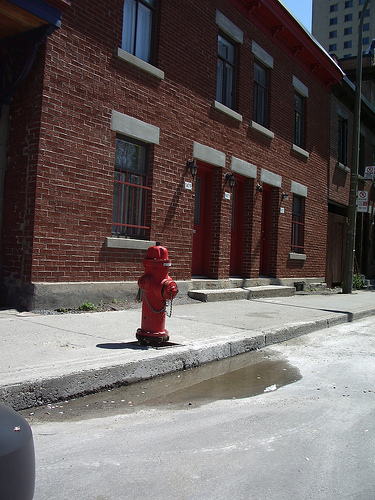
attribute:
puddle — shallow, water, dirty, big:
[21, 347, 301, 424]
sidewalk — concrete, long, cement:
[0, 295, 374, 411]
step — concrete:
[0, 307, 371, 409]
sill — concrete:
[116, 44, 168, 83]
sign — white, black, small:
[186, 181, 196, 192]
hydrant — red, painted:
[135, 241, 178, 348]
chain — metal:
[166, 302, 176, 317]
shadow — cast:
[257, 295, 353, 320]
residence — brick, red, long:
[0, 3, 373, 309]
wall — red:
[30, 0, 110, 283]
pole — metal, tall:
[339, 0, 373, 297]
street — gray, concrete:
[20, 315, 374, 498]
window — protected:
[109, 136, 158, 239]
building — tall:
[315, 1, 374, 81]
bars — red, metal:
[112, 171, 150, 232]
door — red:
[192, 170, 212, 275]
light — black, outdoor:
[191, 158, 200, 173]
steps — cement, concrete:
[188, 287, 297, 303]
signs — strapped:
[356, 186, 368, 209]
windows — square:
[328, 6, 366, 48]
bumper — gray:
[3, 403, 35, 499]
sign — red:
[359, 190, 369, 200]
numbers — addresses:
[185, 181, 288, 217]